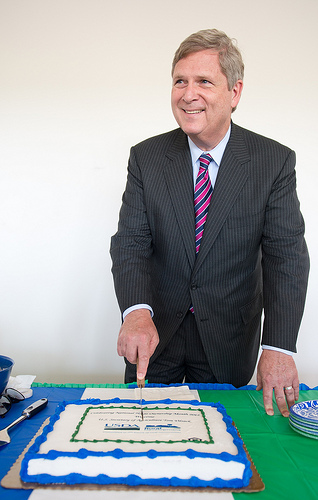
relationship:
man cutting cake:
[110, 28, 309, 416] [19, 397, 252, 488]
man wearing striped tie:
[110, 28, 309, 416] [193, 151, 215, 258]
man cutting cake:
[110, 28, 309, 416] [16, 392, 257, 492]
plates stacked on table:
[289, 399, 317, 439] [0, 385, 317, 498]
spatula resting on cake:
[0, 395, 49, 447] [16, 392, 257, 492]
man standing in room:
[110, 28, 309, 416] [0, 0, 318, 498]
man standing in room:
[110, 28, 309, 416] [0, 0, 317, 406]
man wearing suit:
[110, 28, 309, 416] [104, 115, 311, 392]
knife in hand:
[137, 378, 146, 420] [116, 309, 160, 379]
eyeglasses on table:
[0, 386, 25, 417] [0, 385, 317, 498]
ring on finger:
[285, 385, 291, 388] [283, 383, 293, 407]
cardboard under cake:
[5, 482, 262, 492] [61, 399, 224, 480]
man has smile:
[110, 28, 309, 416] [178, 104, 208, 117]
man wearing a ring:
[110, 28, 309, 419] [284, 383, 293, 392]